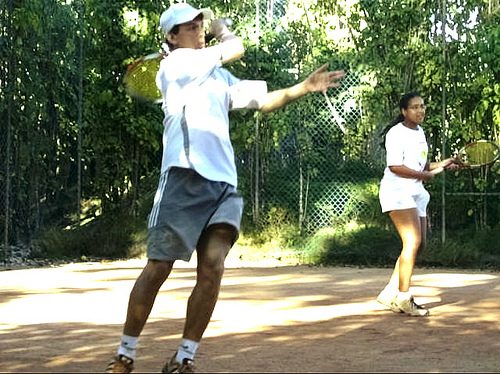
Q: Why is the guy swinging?
A: To play tennis.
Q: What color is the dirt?
A: Brown.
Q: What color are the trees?
A: Green.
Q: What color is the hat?
A: White.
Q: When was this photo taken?
A: Daytime.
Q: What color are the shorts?
A: White & grey.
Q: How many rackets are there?
A: Two.